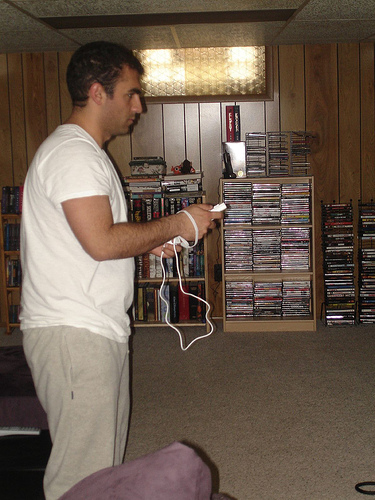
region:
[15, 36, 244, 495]
man playing Wii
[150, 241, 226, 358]
cord hanging down from the Wii controller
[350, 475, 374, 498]
black cord laying on the ground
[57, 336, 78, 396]
thin pocket on the side of the pants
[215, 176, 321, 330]
DVDs stacked on the shelf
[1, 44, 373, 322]
wood paneling on the wall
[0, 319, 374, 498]
carpet on the floor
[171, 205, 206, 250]
white strap around the wrist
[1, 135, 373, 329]
shelving units along the wall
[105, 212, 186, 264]
dark hair on the arm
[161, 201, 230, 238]
The man holds a Wii remote.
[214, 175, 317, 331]
The storage unit for cd 's.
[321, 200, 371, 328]
Storage for DVD's.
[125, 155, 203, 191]
Books sit on a storage unit.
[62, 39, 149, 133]
The man is looking at the screen.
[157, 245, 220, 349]
The cords for the Wii remote.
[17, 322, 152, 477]
The man wears sweatpants.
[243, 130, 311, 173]
Storage for the cd's.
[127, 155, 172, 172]
A floral storage box.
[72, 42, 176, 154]
face of the boy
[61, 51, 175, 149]
face of the man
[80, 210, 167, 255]
hand of the person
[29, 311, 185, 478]
a man wearing pant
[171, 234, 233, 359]
a white near in air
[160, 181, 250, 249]
a man holding machine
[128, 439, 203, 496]
a part of pillow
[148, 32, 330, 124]
a windows with light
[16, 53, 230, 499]
man in a white t-shirt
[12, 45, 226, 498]
man wearing gray sweatpants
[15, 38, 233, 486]
man holding a Wii controller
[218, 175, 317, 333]
shelves of CDs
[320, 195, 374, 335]
shelves of DVDs in cases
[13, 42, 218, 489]
man with short black hair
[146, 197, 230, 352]
white Wii video game controller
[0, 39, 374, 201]
wood paneled walls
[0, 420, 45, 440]
white TV remote controller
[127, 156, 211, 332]
books on a wooden bookshelf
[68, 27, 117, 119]
man has brown hair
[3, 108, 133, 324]
man has white shirt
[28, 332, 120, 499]
man has grey pants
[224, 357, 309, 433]
carpet is light brown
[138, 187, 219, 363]
man holds white controller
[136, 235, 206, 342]
white cord on controller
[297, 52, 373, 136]
wall is dark brown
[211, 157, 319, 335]
brown case with DVDs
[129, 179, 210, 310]
brown bookshelf behind man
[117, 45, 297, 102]
light on top of wall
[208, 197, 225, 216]
a white game controller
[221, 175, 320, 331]
a tall brown bookshelf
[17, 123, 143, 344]
a man's white short sleeve shirt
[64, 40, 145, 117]
short cut black hair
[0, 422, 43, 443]
a gray and black remote control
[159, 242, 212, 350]
a long white cord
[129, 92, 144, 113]
the nose of a man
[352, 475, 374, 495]
Cord on the floor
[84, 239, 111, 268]
Elbow of a man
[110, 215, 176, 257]
Arm of a man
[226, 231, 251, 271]
Large stacks of DVDs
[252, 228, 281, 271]
Large stacks of DVDs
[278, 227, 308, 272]
Large stacks of DVDs